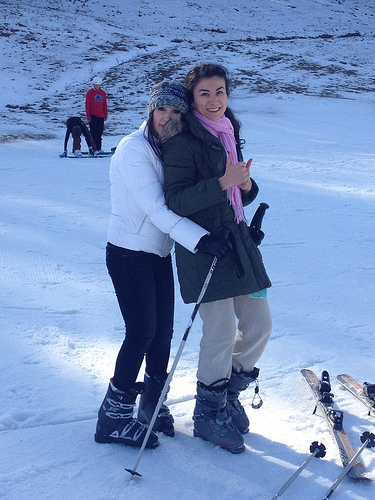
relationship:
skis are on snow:
[130, 444, 159, 465] [283, 276, 337, 338]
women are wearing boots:
[125, 75, 230, 252] [110, 396, 157, 438]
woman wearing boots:
[105, 58, 175, 247] [110, 396, 157, 438]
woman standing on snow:
[105, 58, 175, 247] [283, 276, 337, 338]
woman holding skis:
[105, 58, 175, 247] [130, 444, 159, 465]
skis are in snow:
[130, 444, 159, 465] [283, 276, 337, 338]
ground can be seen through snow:
[242, 10, 293, 43] [283, 276, 337, 338]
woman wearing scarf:
[105, 58, 175, 247] [203, 118, 243, 152]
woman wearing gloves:
[105, 58, 175, 247] [180, 230, 227, 252]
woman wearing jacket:
[105, 58, 175, 247] [93, 167, 153, 231]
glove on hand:
[246, 227, 258, 240] [225, 162, 245, 187]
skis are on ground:
[130, 444, 159, 465] [242, 10, 293, 43]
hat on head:
[145, 84, 194, 113] [201, 67, 217, 81]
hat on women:
[145, 84, 194, 113] [125, 75, 230, 252]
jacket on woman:
[93, 167, 153, 231] [105, 58, 175, 247]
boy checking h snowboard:
[51, 114, 88, 148] [70, 151, 106, 163]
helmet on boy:
[90, 78, 104, 85] [51, 114, 88, 148]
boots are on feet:
[110, 396, 157, 438] [190, 382, 245, 416]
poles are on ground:
[268, 460, 340, 490] [242, 10, 293, 43]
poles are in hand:
[268, 460, 340, 490] [225, 162, 245, 187]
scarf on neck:
[203, 118, 243, 152] [144, 138, 173, 148]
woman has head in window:
[105, 58, 175, 247] [173, 60, 270, 456]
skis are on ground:
[130, 444, 159, 465] [0, 9, 373, 493]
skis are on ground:
[130, 444, 159, 465] [1, 57, 367, 496]